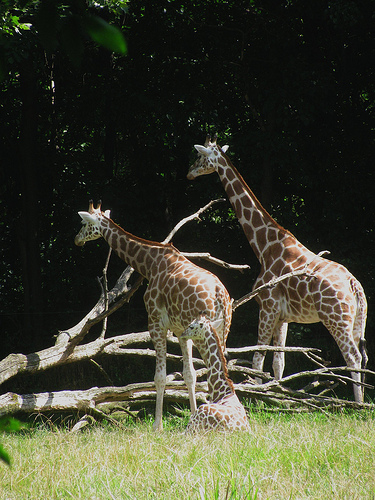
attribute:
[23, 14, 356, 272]
green leaves — trees',  thick,  green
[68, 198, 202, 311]
giraffe —   three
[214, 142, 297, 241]
mane —  brown,   thin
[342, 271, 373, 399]
giraffe tail —  giraffe's,  long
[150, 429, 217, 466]
grass —  blades,  green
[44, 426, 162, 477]
grass —  green and light brown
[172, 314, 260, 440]
giraffe — three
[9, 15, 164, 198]
trees —  tall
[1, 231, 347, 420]
logs —  wood,  Bare 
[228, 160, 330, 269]
brown mane —  brown 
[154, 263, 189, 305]
spots — fur's,  brown and white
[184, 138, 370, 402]
giraffe —  standing up,  large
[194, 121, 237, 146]
horns. —  giraffe's,  brown and black 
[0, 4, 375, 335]
trees — thick,  Dark brown and green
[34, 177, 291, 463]
giraffe —  juvenile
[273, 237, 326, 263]
fur —   brown spotted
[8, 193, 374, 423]
tree —  downed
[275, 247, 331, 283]
spots —  brown and white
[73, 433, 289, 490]
grass —  tall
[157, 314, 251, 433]
giraffe —  three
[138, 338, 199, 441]
legs —  white,  giraffe's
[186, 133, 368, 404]
giraffes —  Two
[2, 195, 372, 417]
logs —  fallen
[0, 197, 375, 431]
branches —  tree's,  fallen